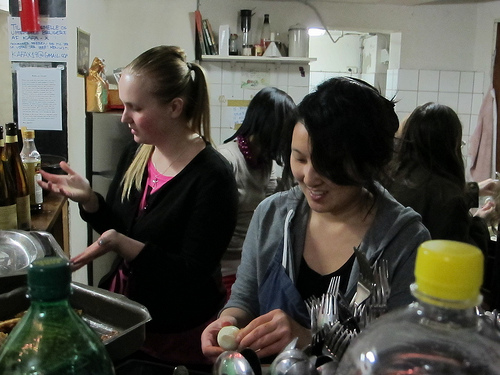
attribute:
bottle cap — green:
[29, 253, 77, 293]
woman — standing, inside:
[229, 114, 404, 335]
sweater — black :
[79, 136, 243, 336]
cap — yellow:
[410, 239, 486, 309]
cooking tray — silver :
[3, 277, 155, 373]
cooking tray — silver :
[2, 225, 70, 288]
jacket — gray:
[240, 181, 440, 338]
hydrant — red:
[19, 0, 39, 34]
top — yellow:
[413, 233, 484, 310]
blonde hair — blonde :
[110, 38, 215, 206]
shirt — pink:
[107, 164, 171, 294]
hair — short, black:
[261, 60, 417, 159]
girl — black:
[231, 70, 489, 284]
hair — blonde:
[114, 37, 234, 208]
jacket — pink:
[458, 88, 498, 199]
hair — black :
[281, 62, 402, 210]